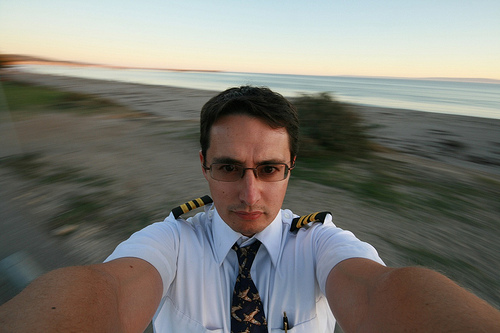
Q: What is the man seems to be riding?
A: A motorcycle.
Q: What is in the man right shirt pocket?
A: Black pen.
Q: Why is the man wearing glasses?
A: See road.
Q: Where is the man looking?
A: Straight ahead.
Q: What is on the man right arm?
A: Two moles.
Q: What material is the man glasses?
A: Metal and glass.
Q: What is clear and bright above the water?
A: The sky.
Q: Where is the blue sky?
A: Above the beach?.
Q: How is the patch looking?
A: It is green.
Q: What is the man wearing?
A: A white shirt.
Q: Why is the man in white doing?
A: Taking a selfie photo.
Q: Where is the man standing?
A: In a field with patch green grass.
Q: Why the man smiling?
A: He is taking a photo.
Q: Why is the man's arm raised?
A: To get a clear focus.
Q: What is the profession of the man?
A: A captain.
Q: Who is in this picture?
A: A man.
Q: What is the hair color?
A: Dark brown.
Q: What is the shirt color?
A: White.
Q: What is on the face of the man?
A: Sunglasses.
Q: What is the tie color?
A: Black and yellow.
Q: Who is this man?
A: Pilot.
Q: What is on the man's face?
A: Sunglasses.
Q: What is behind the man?
A: There is a tree behind the man.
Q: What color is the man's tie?
A: The mans tie is black and gold.